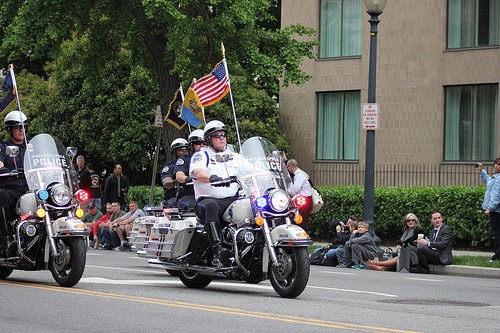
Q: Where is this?
A: This is at the road.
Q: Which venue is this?
A: This is a road.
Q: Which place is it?
A: It is a road.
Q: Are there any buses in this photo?
A: No, there are no buses.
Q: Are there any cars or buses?
A: No, there are no buses or cars.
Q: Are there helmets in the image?
A: Yes, there is a helmet.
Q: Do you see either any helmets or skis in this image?
A: Yes, there is a helmet.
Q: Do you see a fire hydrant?
A: No, there are no fire hydrants.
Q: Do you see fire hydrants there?
A: No, there are no fire hydrants.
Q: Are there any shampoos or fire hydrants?
A: No, there are no fire hydrants or shampoos.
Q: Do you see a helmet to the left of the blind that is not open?
A: Yes, there is a helmet to the left of the blind.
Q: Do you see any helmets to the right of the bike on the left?
A: Yes, there is a helmet to the right of the bike.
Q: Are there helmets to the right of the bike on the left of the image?
A: Yes, there is a helmet to the right of the bike.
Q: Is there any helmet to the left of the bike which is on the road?
A: No, the helmet is to the right of the bike.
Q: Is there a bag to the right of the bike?
A: No, there is a helmet to the right of the bike.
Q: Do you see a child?
A: Yes, there are children.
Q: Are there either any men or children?
A: Yes, there are children.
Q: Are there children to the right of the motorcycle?
A: Yes, there are children to the right of the motorcycle.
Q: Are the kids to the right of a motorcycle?
A: Yes, the kids are to the right of a motorcycle.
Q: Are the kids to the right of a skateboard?
A: No, the kids are to the right of a motorcycle.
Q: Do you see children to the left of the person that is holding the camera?
A: Yes, there are children to the left of the person.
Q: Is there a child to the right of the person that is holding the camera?
A: No, the children are to the left of the person.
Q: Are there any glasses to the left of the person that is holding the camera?
A: No, there are children to the left of the person.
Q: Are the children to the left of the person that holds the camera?
A: Yes, the children are to the left of the person.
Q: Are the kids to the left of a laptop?
A: No, the kids are to the left of the person.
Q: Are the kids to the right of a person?
A: No, the kids are to the left of a person.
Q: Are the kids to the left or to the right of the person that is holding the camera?
A: The kids are to the left of the person.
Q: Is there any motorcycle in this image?
A: Yes, there is a motorcycle.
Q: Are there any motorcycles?
A: Yes, there is a motorcycle.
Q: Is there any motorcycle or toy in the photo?
A: Yes, there is a motorcycle.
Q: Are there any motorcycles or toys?
A: Yes, there is a motorcycle.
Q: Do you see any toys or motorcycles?
A: Yes, there is a motorcycle.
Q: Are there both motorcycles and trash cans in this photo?
A: No, there is a motorcycle but no trash cans.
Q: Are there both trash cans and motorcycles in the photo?
A: No, there is a motorcycle but no trash cans.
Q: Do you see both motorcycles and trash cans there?
A: No, there is a motorcycle but no trash cans.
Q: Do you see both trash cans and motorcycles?
A: No, there is a motorcycle but no trash cans.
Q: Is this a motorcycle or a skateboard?
A: This is a motorcycle.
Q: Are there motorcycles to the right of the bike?
A: Yes, there is a motorcycle to the right of the bike.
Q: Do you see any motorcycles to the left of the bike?
A: No, the motorcycle is to the right of the bike.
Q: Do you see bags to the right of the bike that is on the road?
A: No, there is a motorcycle to the right of the bike.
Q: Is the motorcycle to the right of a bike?
A: Yes, the motorcycle is to the right of a bike.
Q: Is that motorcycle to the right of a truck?
A: No, the motorcycle is to the right of a bike.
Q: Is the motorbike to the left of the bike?
A: No, the motorbike is to the right of the bike.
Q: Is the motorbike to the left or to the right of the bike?
A: The motorbike is to the right of the bike.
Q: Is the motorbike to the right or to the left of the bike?
A: The motorbike is to the right of the bike.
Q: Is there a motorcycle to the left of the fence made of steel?
A: Yes, there is a motorcycle to the left of the fence.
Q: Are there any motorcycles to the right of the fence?
A: No, the motorcycle is to the left of the fence.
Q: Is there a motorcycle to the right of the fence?
A: No, the motorcycle is to the left of the fence.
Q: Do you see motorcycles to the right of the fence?
A: No, the motorcycle is to the left of the fence.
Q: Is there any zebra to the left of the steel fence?
A: No, there is a motorcycle to the left of the fence.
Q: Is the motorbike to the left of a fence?
A: Yes, the motorbike is to the left of a fence.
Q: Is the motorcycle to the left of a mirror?
A: No, the motorcycle is to the left of a fence.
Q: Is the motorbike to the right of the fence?
A: No, the motorbike is to the left of the fence.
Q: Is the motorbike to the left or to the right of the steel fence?
A: The motorbike is to the left of the fence.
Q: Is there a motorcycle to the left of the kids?
A: Yes, there is a motorcycle to the left of the kids.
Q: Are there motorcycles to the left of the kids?
A: Yes, there is a motorcycle to the left of the kids.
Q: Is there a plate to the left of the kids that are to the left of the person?
A: No, there is a motorcycle to the left of the kids.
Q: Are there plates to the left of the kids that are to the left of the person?
A: No, there is a motorcycle to the left of the kids.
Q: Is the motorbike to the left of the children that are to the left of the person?
A: Yes, the motorbike is to the left of the kids.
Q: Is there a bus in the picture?
A: No, there are no buses.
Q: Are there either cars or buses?
A: No, there are no buses or cars.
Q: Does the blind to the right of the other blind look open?
A: Yes, the blind is open.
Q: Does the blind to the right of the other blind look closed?
A: No, the blind is open.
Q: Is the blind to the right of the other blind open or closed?
A: The blind is open.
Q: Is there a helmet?
A: Yes, there is a helmet.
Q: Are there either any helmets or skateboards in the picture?
A: Yes, there is a helmet.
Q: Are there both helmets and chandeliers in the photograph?
A: No, there is a helmet but no chandeliers.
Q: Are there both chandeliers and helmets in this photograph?
A: No, there is a helmet but no chandeliers.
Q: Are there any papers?
A: No, there are no papers.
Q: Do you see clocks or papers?
A: No, there are no papers or clocks.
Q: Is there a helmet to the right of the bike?
A: Yes, there is a helmet to the right of the bike.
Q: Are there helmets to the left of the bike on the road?
A: No, the helmet is to the right of the bike.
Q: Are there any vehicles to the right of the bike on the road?
A: No, there is a helmet to the right of the bike.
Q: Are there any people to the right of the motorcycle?
A: Yes, there are people to the right of the motorcycle.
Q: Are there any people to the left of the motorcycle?
A: No, the people are to the right of the motorcycle.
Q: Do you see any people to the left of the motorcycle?
A: No, the people are to the right of the motorcycle.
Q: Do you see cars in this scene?
A: No, there are no cars.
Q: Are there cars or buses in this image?
A: No, there are no cars or buses.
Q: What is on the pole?
A: The sign is on the pole.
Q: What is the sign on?
A: The sign is on the pole.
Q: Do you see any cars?
A: No, there are no cars.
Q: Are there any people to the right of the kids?
A: Yes, there is a person to the right of the kids.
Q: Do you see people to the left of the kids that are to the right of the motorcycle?
A: No, the person is to the right of the kids.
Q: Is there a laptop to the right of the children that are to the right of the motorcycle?
A: No, there is a person to the right of the kids.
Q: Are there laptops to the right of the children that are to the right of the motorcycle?
A: No, there is a person to the right of the kids.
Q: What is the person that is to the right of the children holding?
A: The person is holding the camera.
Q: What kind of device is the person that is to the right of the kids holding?
A: The person is holding the camera.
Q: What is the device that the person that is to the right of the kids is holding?
A: The device is a camera.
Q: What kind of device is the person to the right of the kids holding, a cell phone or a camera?
A: The person is holding a camera.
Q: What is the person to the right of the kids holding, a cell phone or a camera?
A: The person is holding a camera.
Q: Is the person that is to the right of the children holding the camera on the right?
A: Yes, the person is holding the camera.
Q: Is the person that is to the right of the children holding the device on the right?
A: Yes, the person is holding the camera.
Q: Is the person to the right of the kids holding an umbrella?
A: No, the person is holding the camera.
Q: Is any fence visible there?
A: Yes, there is a fence.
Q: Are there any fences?
A: Yes, there is a fence.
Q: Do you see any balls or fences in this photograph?
A: Yes, there is a fence.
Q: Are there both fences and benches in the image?
A: No, there is a fence but no benches.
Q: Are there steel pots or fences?
A: Yes, there is a steel fence.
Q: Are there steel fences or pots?
A: Yes, there is a steel fence.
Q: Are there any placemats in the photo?
A: No, there are no placemats.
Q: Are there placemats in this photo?
A: No, there are no placemats.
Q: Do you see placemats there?
A: No, there are no placemats.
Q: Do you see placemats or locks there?
A: No, there are no placemats or locks.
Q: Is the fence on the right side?
A: Yes, the fence is on the right of the image.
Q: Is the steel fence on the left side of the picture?
A: No, the fence is on the right of the image.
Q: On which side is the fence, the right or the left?
A: The fence is on the right of the image.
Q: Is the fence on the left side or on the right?
A: The fence is on the right of the image.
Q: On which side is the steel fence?
A: The fence is on the right of the image.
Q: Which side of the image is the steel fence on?
A: The fence is on the right of the image.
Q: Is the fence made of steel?
A: Yes, the fence is made of steel.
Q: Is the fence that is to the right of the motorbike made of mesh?
A: No, the fence is made of steel.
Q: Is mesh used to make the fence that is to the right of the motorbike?
A: No, the fence is made of steel.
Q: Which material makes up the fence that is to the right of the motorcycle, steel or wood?
A: The fence is made of steel.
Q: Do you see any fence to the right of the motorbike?
A: Yes, there is a fence to the right of the motorbike.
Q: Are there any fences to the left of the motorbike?
A: No, the fence is to the right of the motorbike.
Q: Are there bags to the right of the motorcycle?
A: No, there is a fence to the right of the motorcycle.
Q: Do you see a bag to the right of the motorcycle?
A: No, there is a fence to the right of the motorcycle.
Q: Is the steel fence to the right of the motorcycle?
A: Yes, the fence is to the right of the motorcycle.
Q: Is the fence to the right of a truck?
A: No, the fence is to the right of the motorcycle.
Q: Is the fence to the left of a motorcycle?
A: No, the fence is to the right of a motorcycle.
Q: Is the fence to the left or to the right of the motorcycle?
A: The fence is to the right of the motorcycle.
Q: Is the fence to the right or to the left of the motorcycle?
A: The fence is to the right of the motorcycle.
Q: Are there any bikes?
A: Yes, there is a bike.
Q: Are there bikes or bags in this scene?
A: Yes, there is a bike.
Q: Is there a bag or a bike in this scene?
A: Yes, there is a bike.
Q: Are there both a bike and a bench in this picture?
A: No, there is a bike but no benches.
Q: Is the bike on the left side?
A: Yes, the bike is on the left of the image.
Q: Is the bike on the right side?
A: No, the bike is on the left of the image.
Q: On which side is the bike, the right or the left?
A: The bike is on the left of the image.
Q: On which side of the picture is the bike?
A: The bike is on the left of the image.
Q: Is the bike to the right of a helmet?
A: No, the bike is to the left of a helmet.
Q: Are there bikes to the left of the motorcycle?
A: Yes, there is a bike to the left of the motorcycle.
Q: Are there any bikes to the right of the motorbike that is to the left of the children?
A: No, the bike is to the left of the motorcycle.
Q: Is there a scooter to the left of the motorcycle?
A: No, there is a bike to the left of the motorcycle.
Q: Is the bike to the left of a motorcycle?
A: Yes, the bike is to the left of a motorcycle.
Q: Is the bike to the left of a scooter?
A: No, the bike is to the left of a motorcycle.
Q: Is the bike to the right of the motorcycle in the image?
A: No, the bike is to the left of the motorcycle.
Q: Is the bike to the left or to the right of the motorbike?
A: The bike is to the left of the motorbike.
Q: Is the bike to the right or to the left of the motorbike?
A: The bike is to the left of the motorbike.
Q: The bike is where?
A: The bike is on the road.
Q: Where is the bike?
A: The bike is on the road.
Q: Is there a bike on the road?
A: Yes, there is a bike on the road.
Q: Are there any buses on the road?
A: No, there is a bike on the road.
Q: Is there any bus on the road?
A: No, there is a bike on the road.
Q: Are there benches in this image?
A: No, there are no benches.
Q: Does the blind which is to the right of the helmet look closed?
A: Yes, the blind is closed.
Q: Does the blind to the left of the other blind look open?
A: No, the blind is closed.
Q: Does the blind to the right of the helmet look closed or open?
A: The blind is closed.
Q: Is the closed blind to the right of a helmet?
A: Yes, the blind is to the right of a helmet.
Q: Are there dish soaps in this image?
A: No, there are no dish soaps.